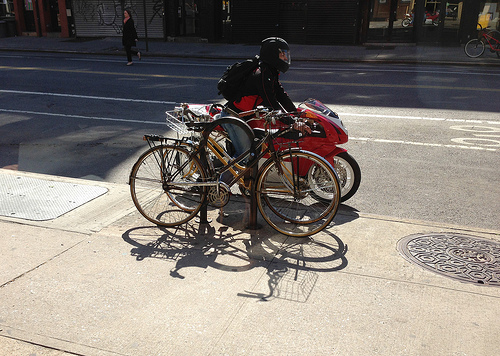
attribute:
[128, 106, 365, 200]
cycle — parked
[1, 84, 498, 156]
lines — white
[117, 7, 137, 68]
woman — walking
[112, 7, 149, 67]
woman — walking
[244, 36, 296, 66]
helmet — BLACK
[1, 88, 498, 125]
lines — white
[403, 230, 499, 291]
manhole cover — metal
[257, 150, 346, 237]
tire — rubber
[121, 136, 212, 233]
tire — rubber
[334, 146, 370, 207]
tire — rubber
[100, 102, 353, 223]
bike — running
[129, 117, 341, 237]
bicycle — parked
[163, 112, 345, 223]
bicycle — parked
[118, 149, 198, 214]
spikes — metal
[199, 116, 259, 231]
pole — curved, metal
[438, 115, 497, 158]
letters — white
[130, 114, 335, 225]
bicycle — yellow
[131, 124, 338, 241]
black bike — chained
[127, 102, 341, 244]
cycle — parked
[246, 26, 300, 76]
helmet — black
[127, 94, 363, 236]
bikes — parked